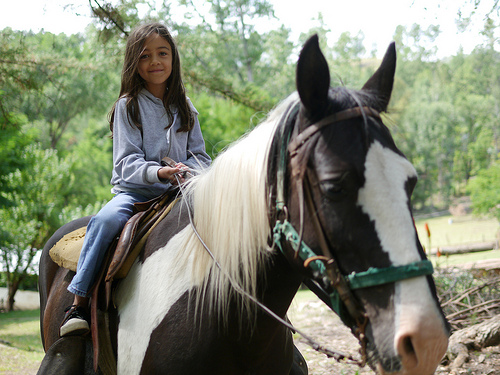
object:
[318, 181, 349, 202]
eye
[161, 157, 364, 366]
bridle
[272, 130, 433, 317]
green bridle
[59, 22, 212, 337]
child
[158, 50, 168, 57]
eye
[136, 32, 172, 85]
face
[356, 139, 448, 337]
stripe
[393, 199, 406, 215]
ground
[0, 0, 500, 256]
trees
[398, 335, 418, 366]
nostril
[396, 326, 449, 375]
nose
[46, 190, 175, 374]
horse's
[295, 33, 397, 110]
two ears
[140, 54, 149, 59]
eye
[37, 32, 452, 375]
horse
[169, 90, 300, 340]
blond mane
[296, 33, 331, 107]
ears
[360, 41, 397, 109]
ears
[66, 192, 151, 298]
pants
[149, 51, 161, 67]
girl nose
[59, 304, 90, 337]
b&w shoes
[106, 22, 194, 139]
brown hair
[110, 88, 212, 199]
gray jacket